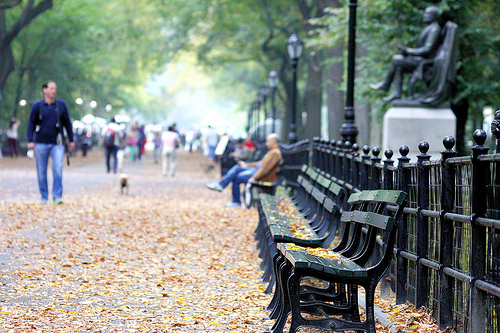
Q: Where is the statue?
A: In the park.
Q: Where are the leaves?
A: On the ground.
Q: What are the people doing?
A: Walking.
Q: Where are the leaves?
A: On ground.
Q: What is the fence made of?
A: Metal.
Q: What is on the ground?
A: Leaves.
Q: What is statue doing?
A: Sitting.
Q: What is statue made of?
A: Bronze.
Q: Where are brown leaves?
A: On sidewalk.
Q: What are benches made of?
A: Iron.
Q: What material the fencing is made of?
A: Iron.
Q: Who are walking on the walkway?
A: People in all walks of life.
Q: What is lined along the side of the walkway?
A: Benches.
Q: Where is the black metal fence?
A: Behind the benches.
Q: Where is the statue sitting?
A: Chair.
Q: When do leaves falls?
A: In the fall.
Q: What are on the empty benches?
A: Leaves.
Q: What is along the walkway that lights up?
A: Lamp posts.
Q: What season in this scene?
A: Fall.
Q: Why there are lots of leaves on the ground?
A: Fall season.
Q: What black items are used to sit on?
A: Benches.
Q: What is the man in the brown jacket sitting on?
A: A bench.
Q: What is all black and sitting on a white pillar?
A: A statue.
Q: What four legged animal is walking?
A: A dog.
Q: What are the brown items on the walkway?
A: Leaves.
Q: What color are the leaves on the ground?
A: Yellow and orange.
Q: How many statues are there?
A: One.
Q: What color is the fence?
A: Black.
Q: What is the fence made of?
A: Metal.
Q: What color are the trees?
A: Green.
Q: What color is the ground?
A: Gray.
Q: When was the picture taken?
A: Daytime.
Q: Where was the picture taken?
A: On a park walkway.